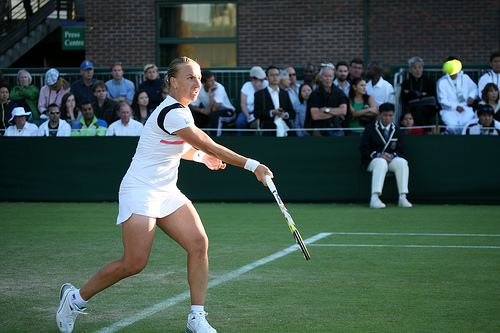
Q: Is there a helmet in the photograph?
A: No, there are no helmets.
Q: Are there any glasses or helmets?
A: No, there are no helmets or glasses.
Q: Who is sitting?
A: The man is sitting.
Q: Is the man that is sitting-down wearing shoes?
A: Yes, the man is wearing shoes.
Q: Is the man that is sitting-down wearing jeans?
A: No, the man is wearing shoes.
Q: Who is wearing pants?
A: The man is wearing pants.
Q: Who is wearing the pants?
A: The man is wearing pants.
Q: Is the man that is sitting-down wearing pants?
A: Yes, the man is wearing pants.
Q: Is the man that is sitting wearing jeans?
A: No, the man is wearing pants.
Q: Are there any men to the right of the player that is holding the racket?
A: Yes, there is a man to the right of the player.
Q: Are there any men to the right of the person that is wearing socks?
A: Yes, there is a man to the right of the player.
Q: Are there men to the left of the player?
A: No, the man is to the right of the player.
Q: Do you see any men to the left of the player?
A: No, the man is to the right of the player.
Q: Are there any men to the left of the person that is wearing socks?
A: No, the man is to the right of the player.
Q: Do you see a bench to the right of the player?
A: No, there is a man to the right of the player.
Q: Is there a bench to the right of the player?
A: No, there is a man to the right of the player.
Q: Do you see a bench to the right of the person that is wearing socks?
A: No, there is a man to the right of the player.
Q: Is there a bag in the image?
A: No, there are no bags.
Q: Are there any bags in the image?
A: No, there are no bags.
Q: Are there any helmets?
A: No, there are no helmets.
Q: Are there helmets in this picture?
A: No, there are no helmets.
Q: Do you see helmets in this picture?
A: No, there are no helmets.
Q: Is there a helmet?
A: No, there are no helmets.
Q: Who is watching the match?
A: The spectators are watching the match.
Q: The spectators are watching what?
A: The spectators are watching the match.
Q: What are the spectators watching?
A: The spectators are watching the match.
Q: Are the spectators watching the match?
A: Yes, the spectators are watching the match.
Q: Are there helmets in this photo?
A: No, there are no helmets.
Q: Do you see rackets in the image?
A: Yes, there is a racket.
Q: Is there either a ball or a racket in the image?
A: Yes, there is a racket.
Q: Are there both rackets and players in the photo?
A: Yes, there are both a racket and a player.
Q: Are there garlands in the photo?
A: No, there are no garlands.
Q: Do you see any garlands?
A: No, there are no garlands.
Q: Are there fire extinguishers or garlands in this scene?
A: No, there are no garlands or fire extinguishers.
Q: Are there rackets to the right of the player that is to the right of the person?
A: Yes, there is a racket to the right of the player.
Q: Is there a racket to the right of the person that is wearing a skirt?
A: Yes, there is a racket to the right of the player.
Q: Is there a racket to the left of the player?
A: No, the racket is to the right of the player.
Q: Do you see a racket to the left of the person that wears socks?
A: No, the racket is to the right of the player.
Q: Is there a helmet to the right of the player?
A: No, there is a racket to the right of the player.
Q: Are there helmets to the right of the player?
A: No, there is a racket to the right of the player.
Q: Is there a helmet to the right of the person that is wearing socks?
A: No, there is a racket to the right of the player.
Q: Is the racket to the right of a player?
A: Yes, the racket is to the right of a player.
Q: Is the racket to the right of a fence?
A: No, the racket is to the right of a player.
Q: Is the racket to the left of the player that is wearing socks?
A: No, the racket is to the right of the player.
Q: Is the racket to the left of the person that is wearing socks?
A: No, the racket is to the right of the player.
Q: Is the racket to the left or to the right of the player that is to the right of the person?
A: The racket is to the right of the player.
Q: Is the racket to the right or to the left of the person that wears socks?
A: The racket is to the right of the player.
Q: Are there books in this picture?
A: No, there are no books.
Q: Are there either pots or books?
A: No, there are no books or pots.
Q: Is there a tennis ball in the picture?
A: Yes, there is a tennis ball.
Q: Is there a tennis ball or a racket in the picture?
A: Yes, there is a tennis ball.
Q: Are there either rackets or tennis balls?
A: Yes, there is a tennis ball.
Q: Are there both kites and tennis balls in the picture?
A: No, there is a tennis ball but no kites.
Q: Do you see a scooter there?
A: No, there are no scooters.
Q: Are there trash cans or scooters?
A: No, there are no scooters or trash cans.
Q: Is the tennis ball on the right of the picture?
A: Yes, the tennis ball is on the right of the image.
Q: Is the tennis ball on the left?
A: No, the tennis ball is on the right of the image.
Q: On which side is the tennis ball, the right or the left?
A: The tennis ball is on the right of the image.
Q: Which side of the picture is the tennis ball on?
A: The tennis ball is on the right of the image.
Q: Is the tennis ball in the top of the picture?
A: Yes, the tennis ball is in the top of the image.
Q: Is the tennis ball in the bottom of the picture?
A: No, the tennis ball is in the top of the image.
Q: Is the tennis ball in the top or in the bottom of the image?
A: The tennis ball is in the top of the image.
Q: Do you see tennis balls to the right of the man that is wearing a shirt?
A: Yes, there is a tennis ball to the right of the man.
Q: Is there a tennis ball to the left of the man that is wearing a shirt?
A: No, the tennis ball is to the right of the man.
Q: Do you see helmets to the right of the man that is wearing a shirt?
A: No, there is a tennis ball to the right of the man.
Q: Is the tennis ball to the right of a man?
A: Yes, the tennis ball is to the right of a man.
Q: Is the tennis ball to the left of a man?
A: No, the tennis ball is to the right of a man.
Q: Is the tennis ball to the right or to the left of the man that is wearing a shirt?
A: The tennis ball is to the right of the man.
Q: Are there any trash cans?
A: No, there are no trash cans.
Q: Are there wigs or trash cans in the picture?
A: No, there are no trash cans or wigs.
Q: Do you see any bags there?
A: No, there are no bags.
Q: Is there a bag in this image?
A: No, there are no bags.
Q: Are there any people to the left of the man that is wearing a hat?
A: Yes, there is a person to the left of the man.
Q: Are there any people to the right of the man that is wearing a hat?
A: No, the person is to the left of the man.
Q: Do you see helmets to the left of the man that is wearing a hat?
A: No, there is a person to the left of the man.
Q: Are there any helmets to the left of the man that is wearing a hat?
A: No, there is a person to the left of the man.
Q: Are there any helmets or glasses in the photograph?
A: No, there are no glasses or helmets.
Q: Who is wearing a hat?
A: The man is wearing a hat.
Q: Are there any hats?
A: Yes, there is a hat.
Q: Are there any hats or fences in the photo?
A: Yes, there is a hat.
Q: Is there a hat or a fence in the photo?
A: Yes, there is a hat.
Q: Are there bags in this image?
A: No, there are no bags.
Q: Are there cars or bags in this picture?
A: No, there are no bags or cars.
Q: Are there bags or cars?
A: No, there are no bags or cars.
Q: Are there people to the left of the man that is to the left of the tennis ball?
A: Yes, there is a person to the left of the man.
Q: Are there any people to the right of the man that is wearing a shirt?
A: No, the person is to the left of the man.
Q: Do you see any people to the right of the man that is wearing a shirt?
A: No, the person is to the left of the man.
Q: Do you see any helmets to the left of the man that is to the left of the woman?
A: No, there is a person to the left of the man.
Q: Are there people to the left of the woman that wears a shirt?
A: Yes, there is a person to the left of the woman.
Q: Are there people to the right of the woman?
A: No, the person is to the left of the woman.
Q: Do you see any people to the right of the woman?
A: No, the person is to the left of the woman.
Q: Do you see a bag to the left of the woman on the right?
A: No, there is a person to the left of the woman.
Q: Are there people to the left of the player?
A: Yes, there is a person to the left of the player.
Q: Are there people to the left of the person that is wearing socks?
A: Yes, there is a person to the left of the player.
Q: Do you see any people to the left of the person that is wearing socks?
A: Yes, there is a person to the left of the player.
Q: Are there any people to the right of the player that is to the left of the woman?
A: No, the person is to the left of the player.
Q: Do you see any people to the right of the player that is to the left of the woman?
A: No, the person is to the left of the player.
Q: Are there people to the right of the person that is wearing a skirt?
A: No, the person is to the left of the player.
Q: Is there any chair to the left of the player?
A: No, there is a person to the left of the player.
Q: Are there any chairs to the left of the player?
A: No, there is a person to the left of the player.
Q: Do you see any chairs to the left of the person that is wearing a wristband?
A: No, there is a person to the left of the player.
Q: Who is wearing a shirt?
A: The man is wearing a shirt.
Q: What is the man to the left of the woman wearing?
A: The man is wearing a shirt.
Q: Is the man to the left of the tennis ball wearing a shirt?
A: Yes, the man is wearing a shirt.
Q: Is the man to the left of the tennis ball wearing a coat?
A: No, the man is wearing a shirt.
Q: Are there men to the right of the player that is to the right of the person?
A: Yes, there is a man to the right of the player.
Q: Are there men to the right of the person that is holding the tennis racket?
A: Yes, there is a man to the right of the player.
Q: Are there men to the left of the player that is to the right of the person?
A: No, the man is to the right of the player.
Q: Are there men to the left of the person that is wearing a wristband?
A: No, the man is to the right of the player.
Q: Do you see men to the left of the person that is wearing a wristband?
A: No, the man is to the right of the player.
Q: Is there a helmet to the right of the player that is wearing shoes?
A: No, there is a man to the right of the player.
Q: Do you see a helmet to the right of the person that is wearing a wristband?
A: No, there is a man to the right of the player.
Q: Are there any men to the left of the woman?
A: Yes, there is a man to the left of the woman.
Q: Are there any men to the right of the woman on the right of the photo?
A: No, the man is to the left of the woman.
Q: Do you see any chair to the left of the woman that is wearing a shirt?
A: No, there is a man to the left of the woman.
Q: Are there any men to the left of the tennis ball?
A: Yes, there is a man to the left of the tennis ball.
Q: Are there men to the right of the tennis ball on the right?
A: No, the man is to the left of the tennis ball.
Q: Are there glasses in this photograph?
A: No, there are no glasses.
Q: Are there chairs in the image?
A: No, there are no chairs.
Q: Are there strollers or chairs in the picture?
A: No, there are no chairs or strollers.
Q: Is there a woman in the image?
A: Yes, there is a woman.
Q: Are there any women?
A: Yes, there is a woman.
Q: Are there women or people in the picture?
A: Yes, there is a woman.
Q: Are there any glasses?
A: No, there are no glasses.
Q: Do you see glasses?
A: No, there are no glasses.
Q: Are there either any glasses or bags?
A: No, there are no glasses or bags.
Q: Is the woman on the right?
A: Yes, the woman is on the right of the image.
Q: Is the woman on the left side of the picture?
A: No, the woman is on the right of the image.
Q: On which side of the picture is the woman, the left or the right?
A: The woman is on the right of the image.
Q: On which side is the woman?
A: The woman is on the right of the image.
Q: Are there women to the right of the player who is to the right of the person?
A: Yes, there is a woman to the right of the player.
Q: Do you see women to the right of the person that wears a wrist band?
A: Yes, there is a woman to the right of the player.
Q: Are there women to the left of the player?
A: No, the woman is to the right of the player.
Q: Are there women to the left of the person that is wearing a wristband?
A: No, the woman is to the right of the player.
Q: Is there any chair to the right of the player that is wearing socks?
A: No, there is a woman to the right of the player.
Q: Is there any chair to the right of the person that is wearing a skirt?
A: No, there is a woman to the right of the player.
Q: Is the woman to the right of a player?
A: Yes, the woman is to the right of a player.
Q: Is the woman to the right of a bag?
A: No, the woman is to the right of a player.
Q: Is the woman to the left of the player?
A: No, the woman is to the right of the player.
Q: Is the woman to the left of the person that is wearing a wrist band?
A: No, the woman is to the right of the player.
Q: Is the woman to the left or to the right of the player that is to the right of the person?
A: The woman is to the right of the player.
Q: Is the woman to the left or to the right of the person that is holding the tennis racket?
A: The woman is to the right of the player.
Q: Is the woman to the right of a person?
A: Yes, the woman is to the right of a person.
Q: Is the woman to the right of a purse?
A: No, the woman is to the right of a person.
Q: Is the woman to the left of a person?
A: No, the woman is to the right of a person.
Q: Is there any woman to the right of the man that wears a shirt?
A: Yes, there is a woman to the right of the man.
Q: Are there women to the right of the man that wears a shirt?
A: Yes, there is a woman to the right of the man.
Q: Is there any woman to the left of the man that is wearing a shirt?
A: No, the woman is to the right of the man.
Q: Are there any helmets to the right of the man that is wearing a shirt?
A: No, there is a woman to the right of the man.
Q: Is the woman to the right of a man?
A: Yes, the woman is to the right of a man.